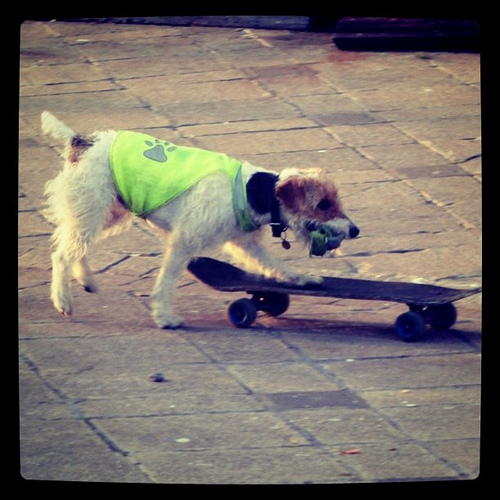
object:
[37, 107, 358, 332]
dog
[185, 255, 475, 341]
skateboard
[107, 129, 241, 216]
vest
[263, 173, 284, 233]
collar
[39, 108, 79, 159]
tail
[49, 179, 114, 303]
leg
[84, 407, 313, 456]
brick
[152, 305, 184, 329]
paw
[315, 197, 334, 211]
eye